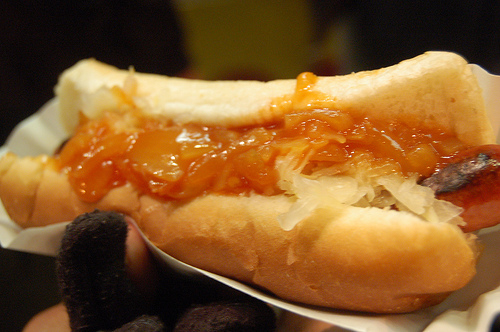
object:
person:
[22, 213, 334, 332]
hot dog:
[13, 130, 500, 234]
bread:
[47, 51, 496, 143]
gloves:
[170, 296, 276, 332]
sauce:
[78, 114, 239, 186]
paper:
[0, 206, 65, 255]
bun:
[0, 150, 478, 313]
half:
[0, 137, 500, 301]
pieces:
[172, 158, 214, 186]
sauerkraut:
[280, 143, 389, 203]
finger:
[116, 218, 149, 286]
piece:
[314, 311, 389, 331]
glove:
[51, 210, 142, 331]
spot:
[431, 151, 491, 192]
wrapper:
[3, 111, 205, 317]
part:
[146, 302, 234, 330]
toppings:
[77, 106, 393, 208]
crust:
[173, 232, 262, 278]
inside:
[385, 88, 450, 125]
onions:
[107, 88, 140, 145]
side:
[41, 161, 127, 219]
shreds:
[372, 178, 451, 213]